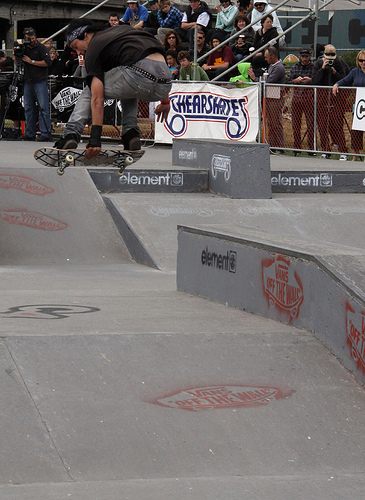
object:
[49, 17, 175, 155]
person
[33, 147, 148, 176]
skateboard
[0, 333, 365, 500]
ramp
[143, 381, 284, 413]
vans logo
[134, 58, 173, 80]
boxers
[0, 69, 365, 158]
fence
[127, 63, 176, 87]
belt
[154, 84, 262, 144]
sign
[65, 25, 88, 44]
headband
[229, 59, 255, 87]
jacket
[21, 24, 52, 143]
man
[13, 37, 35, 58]
video camera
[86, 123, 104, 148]
wristband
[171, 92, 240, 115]
writing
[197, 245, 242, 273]
element logo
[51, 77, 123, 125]
banner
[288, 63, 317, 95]
shirt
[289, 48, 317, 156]
man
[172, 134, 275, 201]
wall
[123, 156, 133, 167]
wheel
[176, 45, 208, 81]
crowd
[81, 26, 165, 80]
shirt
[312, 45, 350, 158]
woman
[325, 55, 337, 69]
camera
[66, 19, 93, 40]
hair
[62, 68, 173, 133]
jeans